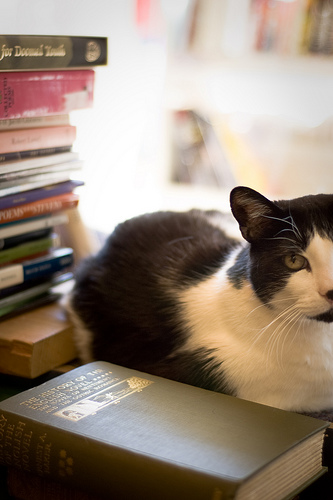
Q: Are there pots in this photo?
A: No, there are no pots.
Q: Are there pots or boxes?
A: No, there are no pots or boxes.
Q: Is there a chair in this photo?
A: No, there are no chairs.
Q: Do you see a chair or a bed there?
A: No, there are no chairs or beds.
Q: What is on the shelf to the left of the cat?
A: The book is on the shelf.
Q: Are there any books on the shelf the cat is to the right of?
A: Yes, there is a book on the shelf.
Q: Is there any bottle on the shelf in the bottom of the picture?
A: No, there is a book on the shelf.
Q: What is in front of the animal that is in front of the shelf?
A: The book is in front of the cat.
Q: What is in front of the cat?
A: The book is in front of the cat.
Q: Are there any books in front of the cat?
A: Yes, there is a book in front of the cat.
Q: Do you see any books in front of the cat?
A: Yes, there is a book in front of the cat.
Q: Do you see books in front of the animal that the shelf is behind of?
A: Yes, there is a book in front of the cat.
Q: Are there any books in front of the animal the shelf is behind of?
A: Yes, there is a book in front of the cat.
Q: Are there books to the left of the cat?
A: Yes, there is a book to the left of the cat.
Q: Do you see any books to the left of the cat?
A: Yes, there is a book to the left of the cat.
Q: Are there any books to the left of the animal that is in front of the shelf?
A: Yes, there is a book to the left of the cat.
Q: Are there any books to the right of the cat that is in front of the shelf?
A: No, the book is to the left of the cat.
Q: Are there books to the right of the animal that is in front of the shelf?
A: No, the book is to the left of the cat.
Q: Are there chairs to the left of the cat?
A: No, there is a book to the left of the cat.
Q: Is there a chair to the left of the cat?
A: No, there is a book to the left of the cat.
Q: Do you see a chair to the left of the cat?
A: No, there is a book to the left of the cat.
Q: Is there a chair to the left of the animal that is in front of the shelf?
A: No, there is a book to the left of the cat.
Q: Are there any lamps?
A: No, there are no lamps.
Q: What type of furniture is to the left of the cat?
A: The piece of furniture is a shelf.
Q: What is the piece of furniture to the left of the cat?
A: The piece of furniture is a shelf.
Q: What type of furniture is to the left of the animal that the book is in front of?
A: The piece of furniture is a shelf.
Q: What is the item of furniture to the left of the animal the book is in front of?
A: The piece of furniture is a shelf.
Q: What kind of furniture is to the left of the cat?
A: The piece of furniture is a shelf.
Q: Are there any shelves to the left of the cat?
A: Yes, there is a shelf to the left of the cat.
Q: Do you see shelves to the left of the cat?
A: Yes, there is a shelf to the left of the cat.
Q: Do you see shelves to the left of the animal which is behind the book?
A: Yes, there is a shelf to the left of the cat.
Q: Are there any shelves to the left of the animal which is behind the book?
A: Yes, there is a shelf to the left of the cat.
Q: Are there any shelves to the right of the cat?
A: No, the shelf is to the left of the cat.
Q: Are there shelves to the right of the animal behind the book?
A: No, the shelf is to the left of the cat.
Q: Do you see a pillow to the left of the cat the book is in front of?
A: No, there is a shelf to the left of the cat.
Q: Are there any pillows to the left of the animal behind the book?
A: No, there is a shelf to the left of the cat.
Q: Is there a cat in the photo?
A: Yes, there is a cat.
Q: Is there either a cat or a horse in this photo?
A: Yes, there is a cat.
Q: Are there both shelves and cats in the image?
A: Yes, there are both a cat and a shelf.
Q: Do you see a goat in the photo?
A: No, there are no goats.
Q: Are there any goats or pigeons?
A: No, there are no goats or pigeons.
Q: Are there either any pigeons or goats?
A: No, there are no goats or pigeons.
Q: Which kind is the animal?
A: The animal is a cat.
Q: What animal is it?
A: The animal is a cat.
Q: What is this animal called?
A: This is a cat.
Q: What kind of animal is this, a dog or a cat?
A: This is a cat.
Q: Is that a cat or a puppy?
A: That is a cat.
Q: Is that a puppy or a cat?
A: That is a cat.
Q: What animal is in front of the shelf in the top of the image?
A: The cat is in front of the shelf.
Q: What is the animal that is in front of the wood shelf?
A: The animal is a cat.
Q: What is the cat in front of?
A: The cat is in front of the shelf.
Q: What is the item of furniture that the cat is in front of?
A: The piece of furniture is a shelf.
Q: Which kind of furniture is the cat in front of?
A: The cat is in front of the shelf.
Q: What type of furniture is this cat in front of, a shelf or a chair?
A: The cat is in front of a shelf.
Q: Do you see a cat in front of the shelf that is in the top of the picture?
A: Yes, there is a cat in front of the shelf.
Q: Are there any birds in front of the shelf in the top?
A: No, there is a cat in front of the shelf.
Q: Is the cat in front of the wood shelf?
A: Yes, the cat is in front of the shelf.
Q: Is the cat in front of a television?
A: No, the cat is in front of the shelf.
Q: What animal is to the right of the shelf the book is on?
A: The animal is a cat.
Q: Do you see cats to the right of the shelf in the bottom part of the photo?
A: Yes, there is a cat to the right of the shelf.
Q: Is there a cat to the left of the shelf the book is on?
A: No, the cat is to the right of the shelf.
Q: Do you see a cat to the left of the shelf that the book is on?
A: No, the cat is to the right of the shelf.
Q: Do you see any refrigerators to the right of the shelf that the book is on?
A: No, there is a cat to the right of the shelf.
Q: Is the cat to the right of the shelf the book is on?
A: Yes, the cat is to the right of the shelf.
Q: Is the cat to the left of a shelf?
A: No, the cat is to the right of a shelf.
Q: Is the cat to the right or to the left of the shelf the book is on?
A: The cat is to the right of the shelf.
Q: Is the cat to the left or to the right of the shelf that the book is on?
A: The cat is to the right of the shelf.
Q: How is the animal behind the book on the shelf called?
A: The animal is a cat.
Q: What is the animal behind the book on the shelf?
A: The animal is a cat.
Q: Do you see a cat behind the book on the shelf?
A: Yes, there is a cat behind the book.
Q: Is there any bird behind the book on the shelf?
A: No, there is a cat behind the book.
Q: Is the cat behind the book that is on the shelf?
A: Yes, the cat is behind the book.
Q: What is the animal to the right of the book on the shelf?
A: The animal is a cat.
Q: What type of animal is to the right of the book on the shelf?
A: The animal is a cat.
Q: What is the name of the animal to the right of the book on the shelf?
A: The animal is a cat.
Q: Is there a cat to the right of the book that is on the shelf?
A: Yes, there is a cat to the right of the book.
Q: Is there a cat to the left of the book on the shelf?
A: No, the cat is to the right of the book.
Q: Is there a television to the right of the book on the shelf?
A: No, there is a cat to the right of the book.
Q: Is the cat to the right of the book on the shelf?
A: Yes, the cat is to the right of the book.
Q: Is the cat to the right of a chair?
A: No, the cat is to the right of the book.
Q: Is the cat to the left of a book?
A: No, the cat is to the right of a book.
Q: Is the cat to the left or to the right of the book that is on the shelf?
A: The cat is to the right of the book.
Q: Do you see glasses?
A: No, there are no glasses.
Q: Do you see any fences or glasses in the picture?
A: No, there are no glasses or fences.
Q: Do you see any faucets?
A: No, there are no faucets.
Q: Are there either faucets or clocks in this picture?
A: No, there are no faucets or clocks.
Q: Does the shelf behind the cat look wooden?
A: Yes, the shelf is wooden.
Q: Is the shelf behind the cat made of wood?
A: Yes, the shelf is made of wood.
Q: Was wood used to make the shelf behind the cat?
A: Yes, the shelf is made of wood.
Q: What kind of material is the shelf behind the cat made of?
A: The shelf is made of wood.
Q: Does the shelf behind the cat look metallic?
A: No, the shelf is wooden.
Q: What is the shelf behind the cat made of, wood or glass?
A: The shelf is made of wood.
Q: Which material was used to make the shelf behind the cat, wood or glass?
A: The shelf is made of wood.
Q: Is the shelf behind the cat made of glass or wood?
A: The shelf is made of wood.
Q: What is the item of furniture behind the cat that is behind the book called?
A: The piece of furniture is a shelf.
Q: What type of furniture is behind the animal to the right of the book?
A: The piece of furniture is a shelf.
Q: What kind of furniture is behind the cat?
A: The piece of furniture is a shelf.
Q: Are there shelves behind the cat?
A: Yes, there is a shelf behind the cat.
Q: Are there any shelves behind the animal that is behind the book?
A: Yes, there is a shelf behind the cat.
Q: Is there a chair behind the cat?
A: No, there is a shelf behind the cat.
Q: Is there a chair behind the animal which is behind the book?
A: No, there is a shelf behind the cat.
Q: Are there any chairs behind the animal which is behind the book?
A: No, there is a shelf behind the cat.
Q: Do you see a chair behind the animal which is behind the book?
A: No, there is a shelf behind the cat.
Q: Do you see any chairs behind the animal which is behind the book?
A: No, there is a shelf behind the cat.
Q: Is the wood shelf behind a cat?
A: Yes, the shelf is behind a cat.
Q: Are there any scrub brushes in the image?
A: No, there are no scrub brushes.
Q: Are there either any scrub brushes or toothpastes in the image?
A: No, there are no scrub brushes or toothpastes.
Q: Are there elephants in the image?
A: No, there are no elephants.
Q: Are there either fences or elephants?
A: No, there are no elephants or fences.